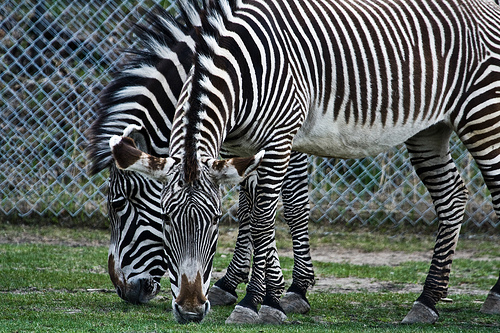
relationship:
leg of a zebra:
[237, 133, 303, 330] [111, 5, 497, 315]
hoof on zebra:
[481, 294, 497, 316] [166, 0, 496, 317]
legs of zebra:
[220, 125, 400, 331] [32, 19, 442, 329]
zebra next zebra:
[84, 7, 173, 312] [166, 0, 496, 317]